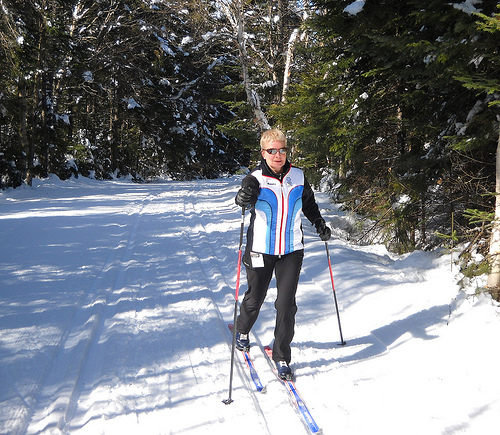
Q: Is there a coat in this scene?
A: Yes, there is a coat.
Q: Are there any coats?
A: Yes, there is a coat.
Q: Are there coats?
A: Yes, there is a coat.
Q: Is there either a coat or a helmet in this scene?
A: Yes, there is a coat.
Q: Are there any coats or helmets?
A: Yes, there is a coat.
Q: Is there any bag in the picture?
A: No, there are no bags.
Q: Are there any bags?
A: No, there are no bags.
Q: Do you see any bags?
A: No, there are no bags.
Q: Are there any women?
A: Yes, there is a woman.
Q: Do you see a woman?
A: Yes, there is a woman.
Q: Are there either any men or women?
A: Yes, there is a woman.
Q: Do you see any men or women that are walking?
A: Yes, the woman is walking.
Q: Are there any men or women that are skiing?
A: Yes, the woman is skiing.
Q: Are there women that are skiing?
A: Yes, there is a woman that is skiing.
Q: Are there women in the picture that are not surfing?
A: Yes, there is a woman that is skiing.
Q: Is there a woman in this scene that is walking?
A: Yes, there is a woman that is walking.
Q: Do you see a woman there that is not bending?
A: Yes, there is a woman that is walking .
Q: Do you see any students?
A: No, there are no students.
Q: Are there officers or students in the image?
A: No, there are no students or officers.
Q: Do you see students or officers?
A: No, there are no students or officers.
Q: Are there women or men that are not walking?
A: No, there is a woman but she is walking.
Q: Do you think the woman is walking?
A: Yes, the woman is walking.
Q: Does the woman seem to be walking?
A: Yes, the woman is walking.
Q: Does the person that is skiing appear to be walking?
A: Yes, the woman is walking.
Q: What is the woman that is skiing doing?
A: The woman is walking.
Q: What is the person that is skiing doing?
A: The woman is walking.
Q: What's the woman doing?
A: The woman is walking.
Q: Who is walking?
A: The woman is walking.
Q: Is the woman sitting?
A: No, the woman is walking.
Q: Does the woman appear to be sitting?
A: No, the woman is walking.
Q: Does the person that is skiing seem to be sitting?
A: No, the woman is walking.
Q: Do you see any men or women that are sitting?
A: No, there is a woman but she is walking.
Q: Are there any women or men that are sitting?
A: No, there is a woman but she is walking.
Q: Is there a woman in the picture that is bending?
A: No, there is a woman but she is walking.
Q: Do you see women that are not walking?
A: No, there is a woman but she is walking.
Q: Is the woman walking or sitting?
A: The woman is walking.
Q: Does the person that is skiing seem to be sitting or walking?
A: The woman is walking.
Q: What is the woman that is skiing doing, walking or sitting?
A: The woman is walking.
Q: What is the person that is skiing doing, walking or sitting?
A: The woman is walking.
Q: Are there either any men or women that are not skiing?
A: No, there is a woman but she is skiing.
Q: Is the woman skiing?
A: Yes, the woman is skiing.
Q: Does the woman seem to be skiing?
A: Yes, the woman is skiing.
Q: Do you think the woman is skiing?
A: Yes, the woman is skiing.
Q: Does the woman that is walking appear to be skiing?
A: Yes, the woman is skiing.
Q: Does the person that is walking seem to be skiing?
A: Yes, the woman is skiing.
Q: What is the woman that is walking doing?
A: The woman is skiing.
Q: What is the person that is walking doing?
A: The woman is skiing.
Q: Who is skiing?
A: The woman is skiing.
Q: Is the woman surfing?
A: No, the woman is skiing.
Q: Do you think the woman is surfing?
A: No, the woman is skiing.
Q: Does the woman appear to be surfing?
A: No, the woman is skiing.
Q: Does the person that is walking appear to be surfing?
A: No, the woman is skiing.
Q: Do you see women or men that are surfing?
A: No, there is a woman but she is skiing.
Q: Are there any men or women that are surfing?
A: No, there is a woman but she is skiing.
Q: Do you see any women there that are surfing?
A: No, there is a woman but she is skiing.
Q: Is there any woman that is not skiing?
A: No, there is a woman but she is skiing.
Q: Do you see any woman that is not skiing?
A: No, there is a woman but she is skiing.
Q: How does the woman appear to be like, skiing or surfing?
A: The woman is skiing.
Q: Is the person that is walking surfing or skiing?
A: The woman is skiing.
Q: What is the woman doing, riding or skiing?
A: The woman is skiing.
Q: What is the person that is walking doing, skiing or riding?
A: The woman is skiing.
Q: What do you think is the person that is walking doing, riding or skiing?
A: The woman is skiing.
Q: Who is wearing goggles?
A: The woman is wearing goggles.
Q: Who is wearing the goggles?
A: The woman is wearing goggles.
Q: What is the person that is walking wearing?
A: The woman is wearing goggles.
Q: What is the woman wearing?
A: The woman is wearing goggles.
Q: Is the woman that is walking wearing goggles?
A: Yes, the woman is wearing goggles.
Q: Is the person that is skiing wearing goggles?
A: Yes, the woman is wearing goggles.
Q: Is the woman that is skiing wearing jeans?
A: No, the woman is wearing goggles.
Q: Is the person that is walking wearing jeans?
A: No, the woman is wearing goggles.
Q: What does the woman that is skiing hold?
A: The woman holds the stick.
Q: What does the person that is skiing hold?
A: The woman holds the stick.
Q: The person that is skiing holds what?
A: The woman holds the stick.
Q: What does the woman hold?
A: The woman holds the stick.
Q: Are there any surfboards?
A: No, there are no surfboards.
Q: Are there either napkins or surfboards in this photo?
A: No, there are no surfboards or napkins.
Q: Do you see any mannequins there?
A: No, there are no mannequins.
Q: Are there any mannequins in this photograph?
A: No, there are no mannequins.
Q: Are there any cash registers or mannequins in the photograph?
A: No, there are no mannequins or cash registers.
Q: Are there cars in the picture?
A: No, there are no cars.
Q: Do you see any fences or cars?
A: No, there are no cars or fences.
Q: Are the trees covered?
A: Yes, the trees are covered.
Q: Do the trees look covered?
A: Yes, the trees are covered.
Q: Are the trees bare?
A: No, the trees are covered.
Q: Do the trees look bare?
A: No, the trees are covered.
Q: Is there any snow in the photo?
A: Yes, there is snow.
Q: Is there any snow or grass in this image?
A: Yes, there is snow.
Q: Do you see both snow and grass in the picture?
A: No, there is snow but no grass.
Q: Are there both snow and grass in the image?
A: No, there is snow but no grass.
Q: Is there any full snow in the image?
A: Yes, there is full snow.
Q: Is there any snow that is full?
A: Yes, there is snow that is full.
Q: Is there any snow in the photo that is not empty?
A: Yes, there is full snow.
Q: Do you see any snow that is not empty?
A: Yes, there is full snow.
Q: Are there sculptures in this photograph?
A: No, there are no sculptures.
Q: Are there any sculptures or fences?
A: No, there are no sculptures or fences.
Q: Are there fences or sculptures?
A: No, there are no sculptures or fences.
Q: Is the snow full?
A: Yes, the snow is full.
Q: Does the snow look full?
A: Yes, the snow is full.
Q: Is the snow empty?
A: No, the snow is full.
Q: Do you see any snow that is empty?
A: No, there is snow but it is full.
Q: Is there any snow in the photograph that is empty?
A: No, there is snow but it is full.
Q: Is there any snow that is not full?
A: No, there is snow but it is full.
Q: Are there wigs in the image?
A: No, there are no wigs.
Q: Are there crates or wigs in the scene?
A: No, there are no wigs or crates.